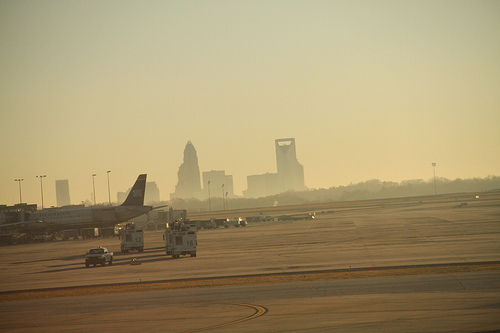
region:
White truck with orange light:
[76, 241, 117, 276]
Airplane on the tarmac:
[5, 161, 160, 249]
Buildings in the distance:
[160, 122, 330, 218]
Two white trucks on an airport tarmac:
[105, 211, 210, 259]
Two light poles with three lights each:
[7, 168, 53, 208]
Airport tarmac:
[0, 180, 498, 322]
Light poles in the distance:
[5, 152, 256, 223]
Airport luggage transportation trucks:
[185, 200, 340, 240]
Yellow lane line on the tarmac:
[111, 276, 319, 326]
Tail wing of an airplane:
[102, 161, 174, 233]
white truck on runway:
[83, 244, 113, 269]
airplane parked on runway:
[3, 170, 159, 240]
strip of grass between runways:
[1, 255, 498, 302]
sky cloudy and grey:
[5, 2, 499, 206]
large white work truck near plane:
[115, 221, 145, 255]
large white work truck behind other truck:
[161, 220, 200, 258]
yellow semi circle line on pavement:
[198, 295, 273, 330]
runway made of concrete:
[1, 267, 499, 330]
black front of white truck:
[85, 255, 104, 263]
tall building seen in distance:
[273, 137, 309, 198]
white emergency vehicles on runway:
[118, 214, 212, 274]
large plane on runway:
[11, 172, 161, 242]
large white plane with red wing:
[13, 165, 162, 243]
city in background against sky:
[28, 105, 498, 220]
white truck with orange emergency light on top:
[81, 238, 122, 268]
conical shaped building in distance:
[178, 134, 207, 204]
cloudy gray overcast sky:
[6, 0, 498, 214]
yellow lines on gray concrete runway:
[11, 253, 498, 331]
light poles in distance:
[13, 163, 125, 216]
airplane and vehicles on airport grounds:
[45, 168, 345, 285]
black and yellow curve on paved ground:
[101, 276, 291, 326]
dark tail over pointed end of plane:
[115, 165, 155, 225]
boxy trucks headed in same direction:
[110, 216, 210, 266]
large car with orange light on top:
[75, 235, 120, 275]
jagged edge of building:
[160, 131, 200, 211]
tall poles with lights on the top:
[11, 160, 123, 215]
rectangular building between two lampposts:
[30, 167, 102, 213]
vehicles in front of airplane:
[20, 195, 111, 245]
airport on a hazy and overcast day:
[22, 17, 447, 303]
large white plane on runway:
[0, 165, 160, 242]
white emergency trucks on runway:
[115, 217, 205, 272]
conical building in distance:
[175, 135, 200, 200]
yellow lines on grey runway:
[5, 230, 496, 325]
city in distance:
[5, 115, 495, 225]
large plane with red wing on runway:
[6, 168, 161, 238]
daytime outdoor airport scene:
[5, 7, 497, 322]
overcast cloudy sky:
[11, 1, 496, 173]